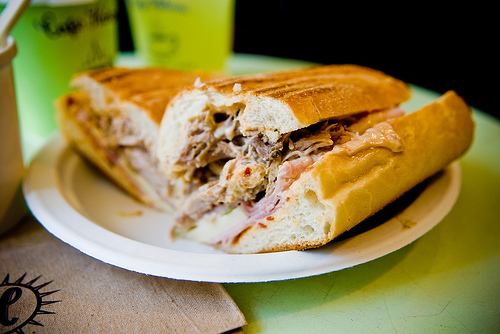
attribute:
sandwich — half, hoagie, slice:
[60, 65, 473, 255]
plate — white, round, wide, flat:
[24, 133, 459, 284]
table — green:
[3, 52, 499, 333]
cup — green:
[1, 0, 119, 137]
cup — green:
[128, 0, 233, 72]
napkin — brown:
[3, 222, 247, 333]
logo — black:
[0, 273, 63, 332]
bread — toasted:
[54, 64, 475, 251]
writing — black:
[32, 3, 117, 40]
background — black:
[114, 3, 498, 120]